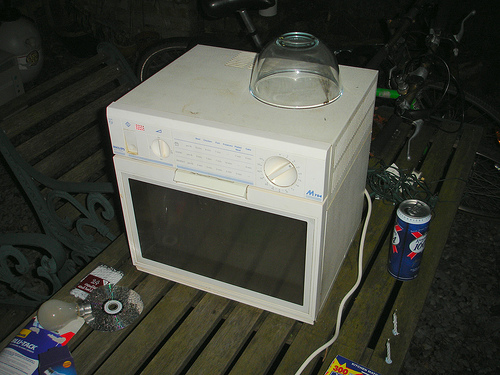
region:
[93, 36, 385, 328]
white microwave oven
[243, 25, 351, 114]
inverted glass mixing bowl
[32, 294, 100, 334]
incandescent light bulb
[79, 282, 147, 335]
compact disc without its case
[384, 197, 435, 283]
red, white, and blue beer can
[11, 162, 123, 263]
ornamental armrest in the style of wrought iron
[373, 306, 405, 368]
two white birthday candles attached to a table with wax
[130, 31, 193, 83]
edge of a bicycle wheel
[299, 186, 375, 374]
power cord of a microwave oven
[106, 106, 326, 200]
dials on the front of a microwave oven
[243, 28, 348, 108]
clear cup sitting on oven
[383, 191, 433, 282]
opened beer can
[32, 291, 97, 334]
light bulb with silver base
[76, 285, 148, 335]
old cracked CD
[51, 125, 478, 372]
objects sitting on wooden bench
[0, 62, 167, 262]
old iron and wood bench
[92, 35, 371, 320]
oven door is closed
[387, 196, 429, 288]
can is blue with white and red designs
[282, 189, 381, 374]
oven white power cord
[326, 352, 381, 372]
this is a book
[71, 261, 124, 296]
this is a book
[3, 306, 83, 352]
this is a book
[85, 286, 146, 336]
this is a compact disk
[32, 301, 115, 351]
this is a bulb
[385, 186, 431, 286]
this is a can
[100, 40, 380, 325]
this is a microwave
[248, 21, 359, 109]
this is a clear glass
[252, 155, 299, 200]
this is the adjusting knob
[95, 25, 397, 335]
the microwave is white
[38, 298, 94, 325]
white glass light bulb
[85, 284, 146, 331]
compact disc under light bulb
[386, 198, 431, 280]
blue can on table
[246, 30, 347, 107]
inverted clear glass bowl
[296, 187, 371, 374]
long white electrical cord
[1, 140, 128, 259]
metal arm rest on chair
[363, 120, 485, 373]
brown wooden slat on table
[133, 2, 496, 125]
bicycle behind table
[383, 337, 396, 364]
birthday candle on table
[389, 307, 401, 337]
birthday candle is white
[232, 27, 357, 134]
an upside down glass bowl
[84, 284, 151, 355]
silver cd on table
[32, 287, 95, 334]
light bulb on table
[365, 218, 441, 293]
a tall canned beverage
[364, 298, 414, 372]
two pieces of white rope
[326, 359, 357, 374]
the red number 300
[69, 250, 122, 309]
maroon and white pack of cigs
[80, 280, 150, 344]
a cracked cd on table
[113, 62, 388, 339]
white microwave on table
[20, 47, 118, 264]
metal and wooden chair